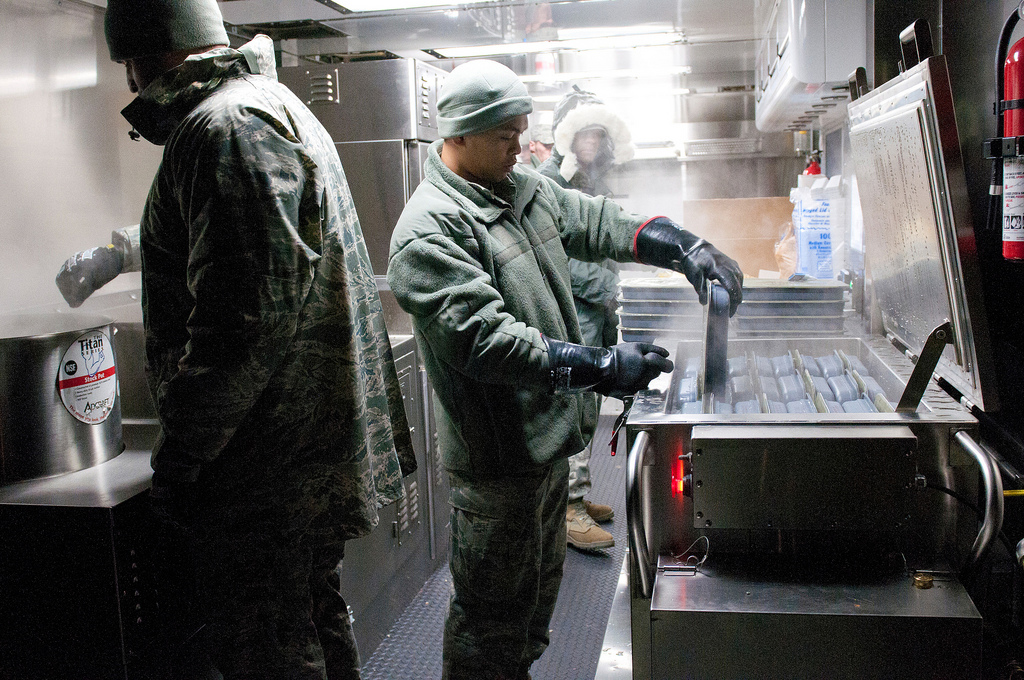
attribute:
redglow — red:
[669, 447, 689, 498]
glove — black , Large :
[545, 339, 675, 390]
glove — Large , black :
[637, 213, 742, 315]